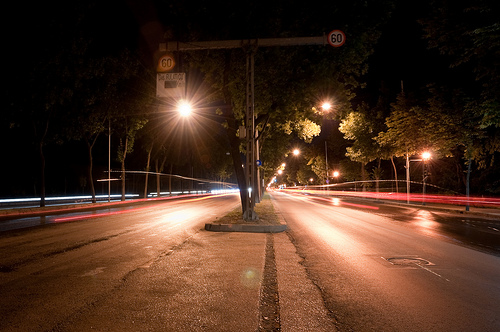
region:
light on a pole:
[408, 143, 435, 165]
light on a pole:
[324, 166, 341, 183]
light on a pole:
[314, 95, 337, 116]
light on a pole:
[292, 145, 304, 159]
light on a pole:
[169, 93, 196, 118]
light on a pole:
[278, 159, 286, 167]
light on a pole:
[276, 168, 288, 175]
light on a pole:
[269, 175, 280, 180]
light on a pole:
[267, 180, 278, 185]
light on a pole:
[238, 160, 244, 167]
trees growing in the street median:
[214, 117, 285, 248]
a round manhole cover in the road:
[381, 247, 433, 272]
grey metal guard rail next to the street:
[8, 194, 149, 222]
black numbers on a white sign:
[328, 31, 344, 46]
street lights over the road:
[270, 97, 346, 212]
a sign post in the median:
[134, 24, 382, 248]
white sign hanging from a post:
[146, 68, 195, 101]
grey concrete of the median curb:
[212, 222, 277, 235]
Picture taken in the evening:
[17, 13, 479, 314]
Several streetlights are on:
[161, 77, 472, 217]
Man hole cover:
[372, 225, 443, 279]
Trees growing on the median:
[222, 80, 276, 222]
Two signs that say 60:
[143, 27, 361, 75]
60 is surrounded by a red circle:
[144, 15, 370, 71]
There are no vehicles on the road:
[55, 165, 407, 298]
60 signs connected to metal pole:
[149, 26, 370, 212]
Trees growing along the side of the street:
[42, 103, 217, 199]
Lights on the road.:
[125, 36, 446, 271]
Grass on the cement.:
[151, 165, 355, 294]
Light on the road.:
[291, 160, 434, 324]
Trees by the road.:
[49, 59, 214, 245]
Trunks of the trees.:
[344, 88, 481, 241]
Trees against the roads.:
[64, 35, 219, 205]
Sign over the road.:
[130, 16, 415, 100]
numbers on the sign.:
[131, 39, 226, 116]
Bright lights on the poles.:
[308, 63, 476, 265]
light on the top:
[156, 63, 220, 134]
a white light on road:
[282, 181, 374, 286]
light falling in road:
[286, 178, 383, 275]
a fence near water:
[87, 123, 220, 210]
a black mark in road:
[235, 206, 285, 328]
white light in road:
[276, 78, 496, 225]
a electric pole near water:
[123, 60, 215, 186]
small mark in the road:
[290, 236, 347, 330]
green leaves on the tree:
[424, 127, 434, 142]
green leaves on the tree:
[349, 118, 362, 139]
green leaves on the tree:
[433, 100, 495, 157]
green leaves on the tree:
[371, 114, 423, 131]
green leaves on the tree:
[290, 111, 315, 153]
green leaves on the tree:
[294, 127, 304, 142]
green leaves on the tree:
[266, 138, 273, 178]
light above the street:
[286, 79, 373, 136]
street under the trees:
[301, 203, 417, 283]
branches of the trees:
[329, 155, 430, 197]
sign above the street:
[136, 66, 214, 114]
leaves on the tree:
[363, 100, 473, 160]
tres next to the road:
[312, 112, 475, 189]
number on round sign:
[301, 18, 370, 68]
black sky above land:
[9, 18, 84, 60]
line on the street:
[408, 258, 449, 298]